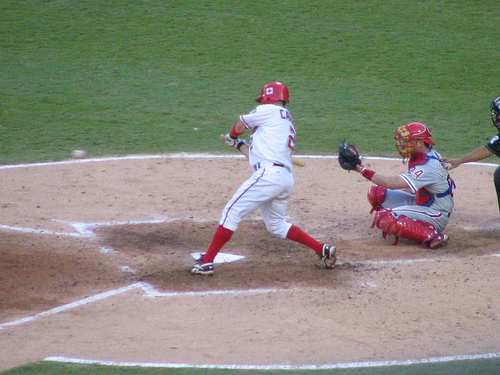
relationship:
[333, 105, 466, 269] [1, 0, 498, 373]
catcher crouching on ground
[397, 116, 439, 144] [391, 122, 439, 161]
helmet on head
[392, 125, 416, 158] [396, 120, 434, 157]
mask on catchers head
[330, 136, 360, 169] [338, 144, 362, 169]
mitt on catchers hand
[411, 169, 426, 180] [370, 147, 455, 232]
4 on jersey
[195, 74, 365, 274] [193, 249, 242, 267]
batter at plate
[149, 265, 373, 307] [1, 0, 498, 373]
lines on ground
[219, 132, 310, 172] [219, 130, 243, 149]
bat in batters hands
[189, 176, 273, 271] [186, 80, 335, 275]
right leg on batter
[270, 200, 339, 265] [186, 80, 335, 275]
left leg on batter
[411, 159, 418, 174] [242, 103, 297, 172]
number 2 on jersey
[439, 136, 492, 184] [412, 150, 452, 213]
umpire's hand on catchers back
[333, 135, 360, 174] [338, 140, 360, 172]
catcher's glove on catchers hand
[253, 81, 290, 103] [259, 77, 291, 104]
red helmet on batters head